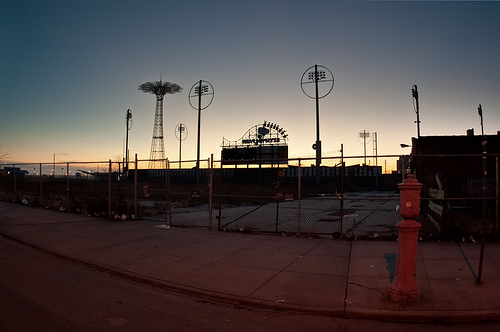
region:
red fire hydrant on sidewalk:
[386, 168, 417, 298]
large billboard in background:
[215, 113, 292, 173]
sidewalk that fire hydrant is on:
[2, 200, 494, 312]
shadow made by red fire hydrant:
[385, 248, 404, 283]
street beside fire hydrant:
[10, 238, 474, 330]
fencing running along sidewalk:
[17, 156, 496, 237]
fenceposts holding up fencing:
[7, 165, 479, 235]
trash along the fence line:
[25, 193, 155, 222]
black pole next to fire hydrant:
[466, 104, 489, 285]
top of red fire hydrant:
[398, 165, 416, 183]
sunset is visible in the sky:
[64, 115, 143, 204]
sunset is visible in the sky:
[154, 133, 236, 188]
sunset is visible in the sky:
[302, 135, 416, 202]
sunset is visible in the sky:
[298, 118, 387, 167]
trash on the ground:
[34, 193, 149, 234]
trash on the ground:
[271, 222, 346, 245]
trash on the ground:
[427, 222, 477, 257]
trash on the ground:
[108, 196, 162, 226]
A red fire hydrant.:
[385, 169, 428, 307]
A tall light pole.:
[298, 61, 337, 200]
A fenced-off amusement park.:
[0, 60, 498, 255]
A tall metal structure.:
[135, 71, 183, 171]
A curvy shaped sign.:
[220, 117, 290, 165]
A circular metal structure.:
[298, 60, 335, 100]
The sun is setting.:
[1, 1, 496, 180]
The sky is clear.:
[5, 3, 492, 58]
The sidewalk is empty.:
[2, 195, 496, 330]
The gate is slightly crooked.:
[133, 154, 215, 234]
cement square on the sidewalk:
[297, 256, 344, 273]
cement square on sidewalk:
[274, 277, 339, 307]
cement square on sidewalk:
[210, 266, 267, 293]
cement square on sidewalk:
[150, 257, 195, 273]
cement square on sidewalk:
[191, 244, 230, 259]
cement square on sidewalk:
[197, 223, 249, 246]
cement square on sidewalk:
[436, 280, 477, 315]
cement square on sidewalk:
[431, 258, 455, 276]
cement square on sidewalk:
[422, 240, 447, 259]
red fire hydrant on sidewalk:
[400, 185, 426, 319]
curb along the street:
[5, 232, 393, 324]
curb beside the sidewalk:
[2, 230, 378, 317]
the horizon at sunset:
[9, 118, 432, 207]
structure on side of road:
[384, 164, 426, 329]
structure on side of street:
[380, 161, 432, 308]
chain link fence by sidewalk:
[124, 153, 389, 232]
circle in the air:
[295, 52, 336, 111]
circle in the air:
[180, 76, 216, 115]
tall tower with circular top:
[137, 75, 186, 187]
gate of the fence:
[155, 152, 225, 230]